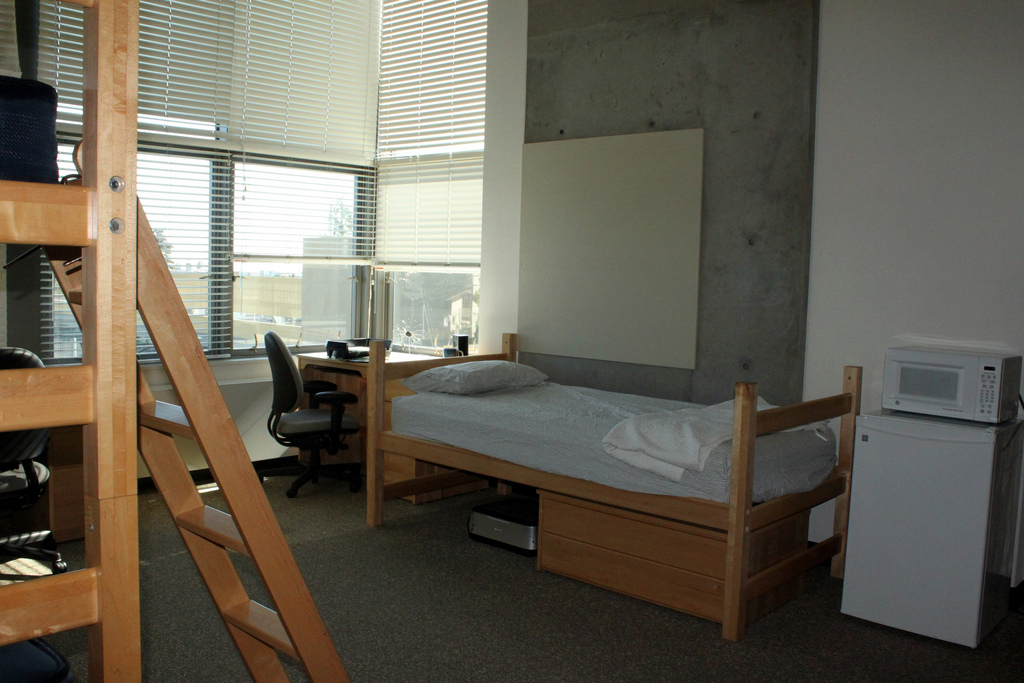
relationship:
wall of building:
[669, 22, 894, 405] [97, 18, 996, 593]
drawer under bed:
[536, 490, 815, 624] [348, 327, 863, 643]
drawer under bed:
[521, 517, 742, 638] [348, 327, 863, 643]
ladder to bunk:
[30, 135, 342, 678] [7, 18, 70, 176]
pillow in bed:
[402, 360, 550, 395] [348, 327, 863, 643]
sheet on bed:
[596, 383, 789, 479] [348, 327, 863, 643]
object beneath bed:
[456, 482, 545, 556] [348, 327, 863, 643]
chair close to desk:
[253, 325, 372, 509] [283, 338, 461, 507]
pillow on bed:
[398, 351, 550, 404] [348, 327, 863, 643]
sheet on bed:
[600, 395, 832, 483] [348, 327, 863, 643]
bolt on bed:
[98, 161, 151, 196] [3, 264, 192, 578]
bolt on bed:
[96, 212, 136, 238] [39, 156, 184, 440]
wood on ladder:
[214, 588, 320, 647] [176, 458, 317, 634]